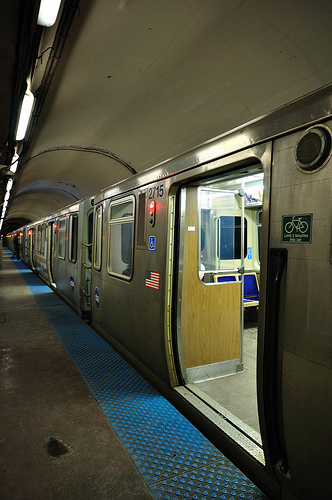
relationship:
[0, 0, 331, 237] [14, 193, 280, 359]
ceiling in subway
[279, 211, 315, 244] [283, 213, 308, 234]
sign showing bicycle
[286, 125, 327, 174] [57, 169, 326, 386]
speaker on side of train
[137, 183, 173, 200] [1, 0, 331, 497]
number 2715 on side of subway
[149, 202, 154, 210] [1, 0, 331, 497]
light on side of subway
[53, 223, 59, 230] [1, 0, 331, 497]
light on side of subway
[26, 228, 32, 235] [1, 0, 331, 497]
light on side of subway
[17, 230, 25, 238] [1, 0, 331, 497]
light on side of subway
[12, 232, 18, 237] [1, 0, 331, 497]
light on side of subway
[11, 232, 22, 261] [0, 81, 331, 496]
man getting on subway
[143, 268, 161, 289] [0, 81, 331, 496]
flag on subway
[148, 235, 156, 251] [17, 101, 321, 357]
sign on subway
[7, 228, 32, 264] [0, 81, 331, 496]
man entering subway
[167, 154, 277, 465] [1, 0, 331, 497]
entrance on subway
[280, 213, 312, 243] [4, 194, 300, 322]
sign on train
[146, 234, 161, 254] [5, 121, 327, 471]
sign on train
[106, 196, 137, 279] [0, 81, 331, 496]
passenger window on subway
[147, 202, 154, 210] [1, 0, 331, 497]
light on side of subway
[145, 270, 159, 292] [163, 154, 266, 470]
flag beside door